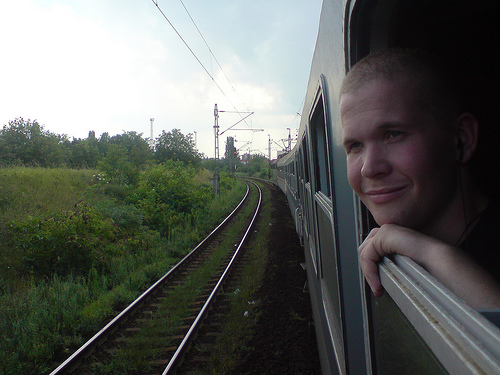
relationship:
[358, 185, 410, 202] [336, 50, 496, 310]
mouth on person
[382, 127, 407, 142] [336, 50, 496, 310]
eye on person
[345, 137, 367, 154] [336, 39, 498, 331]
eye on person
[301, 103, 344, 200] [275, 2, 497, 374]
window on train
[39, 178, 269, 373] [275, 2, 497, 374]
tracks near train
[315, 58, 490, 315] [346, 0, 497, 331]
person leaning out window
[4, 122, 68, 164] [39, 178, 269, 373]
bush near tracks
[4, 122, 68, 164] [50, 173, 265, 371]
bush near track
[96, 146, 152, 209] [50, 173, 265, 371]
bush near track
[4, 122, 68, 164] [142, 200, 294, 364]
bush near tracks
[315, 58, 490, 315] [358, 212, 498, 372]
person holding onto ledge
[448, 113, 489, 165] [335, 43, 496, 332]
ear on man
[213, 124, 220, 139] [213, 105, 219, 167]
part of pole